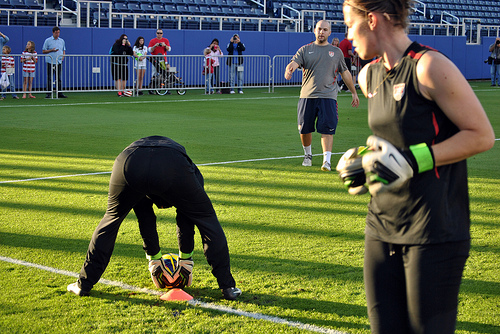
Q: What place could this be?
A: It is a field.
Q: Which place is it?
A: It is a field.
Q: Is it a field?
A: Yes, it is a field.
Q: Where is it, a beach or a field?
A: It is a field.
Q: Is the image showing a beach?
A: No, the picture is showing a field.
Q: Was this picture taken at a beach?
A: No, the picture was taken in a field.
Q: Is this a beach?
A: No, it is a field.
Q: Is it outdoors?
A: Yes, it is outdoors.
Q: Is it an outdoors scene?
A: Yes, it is outdoors.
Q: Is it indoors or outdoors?
A: It is outdoors.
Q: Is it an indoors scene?
A: No, it is outdoors.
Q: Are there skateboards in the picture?
A: No, there are no skateboards.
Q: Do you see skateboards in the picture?
A: No, there are no skateboards.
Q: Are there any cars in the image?
A: No, there are no cars.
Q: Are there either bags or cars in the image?
A: No, there are no cars or bags.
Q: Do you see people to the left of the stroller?
A: Yes, there is a person to the left of the stroller.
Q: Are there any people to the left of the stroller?
A: Yes, there is a person to the left of the stroller.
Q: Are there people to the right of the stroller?
A: No, the person is to the left of the stroller.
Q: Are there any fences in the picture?
A: Yes, there is a fence.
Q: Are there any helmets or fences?
A: Yes, there is a fence.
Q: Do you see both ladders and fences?
A: No, there is a fence but no ladders.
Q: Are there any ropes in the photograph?
A: No, there are no ropes.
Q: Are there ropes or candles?
A: No, there are no ropes or candles.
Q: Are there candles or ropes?
A: No, there are no ropes or candles.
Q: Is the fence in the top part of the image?
A: Yes, the fence is in the top of the image.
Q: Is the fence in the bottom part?
A: No, the fence is in the top of the image.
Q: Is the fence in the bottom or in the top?
A: The fence is in the top of the image.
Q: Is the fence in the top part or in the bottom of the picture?
A: The fence is in the top of the image.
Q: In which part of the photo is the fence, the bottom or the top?
A: The fence is in the top of the image.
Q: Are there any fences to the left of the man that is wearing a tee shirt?
A: Yes, there is a fence to the left of the man.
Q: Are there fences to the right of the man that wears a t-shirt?
A: No, the fence is to the left of the man.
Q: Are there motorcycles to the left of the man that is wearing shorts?
A: No, there is a fence to the left of the man.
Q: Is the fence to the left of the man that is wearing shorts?
A: Yes, the fence is to the left of the man.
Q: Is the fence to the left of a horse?
A: No, the fence is to the left of the man.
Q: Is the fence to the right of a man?
A: No, the fence is to the left of a man.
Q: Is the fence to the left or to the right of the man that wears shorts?
A: The fence is to the left of the man.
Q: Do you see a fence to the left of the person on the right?
A: Yes, there is a fence to the left of the person.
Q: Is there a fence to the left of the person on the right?
A: Yes, there is a fence to the left of the person.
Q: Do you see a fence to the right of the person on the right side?
A: No, the fence is to the left of the person.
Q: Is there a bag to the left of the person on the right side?
A: No, there is a fence to the left of the person.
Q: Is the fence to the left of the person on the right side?
A: Yes, the fence is to the left of the person.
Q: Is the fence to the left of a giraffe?
A: No, the fence is to the left of the person.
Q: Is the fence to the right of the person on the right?
A: No, the fence is to the left of the person.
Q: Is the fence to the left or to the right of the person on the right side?
A: The fence is to the left of the person.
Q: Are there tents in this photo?
A: No, there are no tents.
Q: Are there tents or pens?
A: No, there are no tents or pens.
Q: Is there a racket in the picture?
A: No, there are no rackets.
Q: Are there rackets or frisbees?
A: No, there are no rackets or frisbees.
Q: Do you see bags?
A: No, there are no bags.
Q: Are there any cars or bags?
A: No, there are no bags or cars.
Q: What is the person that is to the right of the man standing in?
A: The person is standing in the grass.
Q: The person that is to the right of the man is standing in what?
A: The person is standing in the grass.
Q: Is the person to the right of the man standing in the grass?
A: Yes, the person is standing in the grass.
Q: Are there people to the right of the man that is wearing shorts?
A: Yes, there is a person to the right of the man.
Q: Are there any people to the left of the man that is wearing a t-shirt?
A: No, the person is to the right of the man.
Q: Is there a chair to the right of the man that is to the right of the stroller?
A: No, there is a person to the right of the man.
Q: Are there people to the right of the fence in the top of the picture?
A: Yes, there is a person to the right of the fence.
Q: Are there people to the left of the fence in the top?
A: No, the person is to the right of the fence.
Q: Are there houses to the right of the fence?
A: No, there is a person to the right of the fence.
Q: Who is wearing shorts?
A: The man is wearing shorts.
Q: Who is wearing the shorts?
A: The man is wearing shorts.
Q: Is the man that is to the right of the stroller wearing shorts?
A: Yes, the man is wearing shorts.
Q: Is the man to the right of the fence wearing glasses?
A: No, the man is wearing shorts.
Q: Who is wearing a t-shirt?
A: The man is wearing a t-shirt.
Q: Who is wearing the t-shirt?
A: The man is wearing a t-shirt.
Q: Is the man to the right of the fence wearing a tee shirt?
A: Yes, the man is wearing a tee shirt.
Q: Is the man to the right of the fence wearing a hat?
A: No, the man is wearing a tee shirt.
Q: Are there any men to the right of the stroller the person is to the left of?
A: Yes, there is a man to the right of the stroller.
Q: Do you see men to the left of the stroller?
A: No, the man is to the right of the stroller.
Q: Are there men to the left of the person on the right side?
A: Yes, there is a man to the left of the person.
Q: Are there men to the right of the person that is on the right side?
A: No, the man is to the left of the person.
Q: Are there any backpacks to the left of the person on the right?
A: No, there is a man to the left of the person.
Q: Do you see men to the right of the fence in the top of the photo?
A: Yes, there is a man to the right of the fence.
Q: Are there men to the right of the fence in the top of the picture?
A: Yes, there is a man to the right of the fence.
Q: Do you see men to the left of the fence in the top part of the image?
A: No, the man is to the right of the fence.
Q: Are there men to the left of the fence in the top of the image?
A: No, the man is to the right of the fence.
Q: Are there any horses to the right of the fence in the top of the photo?
A: No, there is a man to the right of the fence.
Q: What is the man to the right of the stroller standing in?
A: The man is standing in the grass.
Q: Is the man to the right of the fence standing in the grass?
A: Yes, the man is standing in the grass.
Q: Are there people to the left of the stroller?
A: Yes, there is a person to the left of the stroller.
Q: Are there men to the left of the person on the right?
A: Yes, there is a man to the left of the person.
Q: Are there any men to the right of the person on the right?
A: No, the man is to the left of the person.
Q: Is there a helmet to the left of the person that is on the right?
A: No, there is a man to the left of the person.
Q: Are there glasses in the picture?
A: No, there are no glasses.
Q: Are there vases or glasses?
A: No, there are no glasses or vases.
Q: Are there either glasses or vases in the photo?
A: No, there are no glasses or vases.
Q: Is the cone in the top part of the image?
A: No, the cone is in the bottom of the image.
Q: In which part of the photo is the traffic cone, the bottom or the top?
A: The traffic cone is in the bottom of the image.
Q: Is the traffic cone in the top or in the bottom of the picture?
A: The traffic cone is in the bottom of the image.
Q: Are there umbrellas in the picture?
A: No, there are no umbrellas.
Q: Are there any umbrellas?
A: No, there are no umbrellas.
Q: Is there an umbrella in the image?
A: No, there are no umbrellas.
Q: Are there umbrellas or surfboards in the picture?
A: No, there are no umbrellas or surfboards.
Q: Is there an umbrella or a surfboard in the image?
A: No, there are no umbrellas or surfboards.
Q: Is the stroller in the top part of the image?
A: Yes, the stroller is in the top of the image.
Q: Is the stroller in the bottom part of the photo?
A: No, the stroller is in the top of the image.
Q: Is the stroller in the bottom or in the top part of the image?
A: The stroller is in the top of the image.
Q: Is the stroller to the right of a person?
A: Yes, the stroller is to the right of a person.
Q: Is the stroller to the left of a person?
A: No, the stroller is to the right of a person.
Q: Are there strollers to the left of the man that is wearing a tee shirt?
A: Yes, there is a stroller to the left of the man.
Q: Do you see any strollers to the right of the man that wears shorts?
A: No, the stroller is to the left of the man.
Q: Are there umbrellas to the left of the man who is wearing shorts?
A: No, there is a stroller to the left of the man.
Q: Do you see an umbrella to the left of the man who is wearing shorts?
A: No, there is a stroller to the left of the man.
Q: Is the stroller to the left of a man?
A: Yes, the stroller is to the left of a man.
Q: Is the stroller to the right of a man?
A: No, the stroller is to the left of a man.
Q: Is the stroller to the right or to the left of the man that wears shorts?
A: The stroller is to the left of the man.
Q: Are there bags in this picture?
A: No, there are no bags.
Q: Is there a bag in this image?
A: No, there are no bags.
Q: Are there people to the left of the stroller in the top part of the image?
A: Yes, there is a person to the left of the stroller.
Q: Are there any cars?
A: No, there are no cars.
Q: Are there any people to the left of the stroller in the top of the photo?
A: Yes, there is a person to the left of the stroller.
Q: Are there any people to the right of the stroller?
A: No, the person is to the left of the stroller.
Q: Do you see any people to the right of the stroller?
A: No, the person is to the left of the stroller.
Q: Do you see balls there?
A: Yes, there is a ball.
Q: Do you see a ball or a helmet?
A: Yes, there is a ball.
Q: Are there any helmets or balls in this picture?
A: Yes, there is a ball.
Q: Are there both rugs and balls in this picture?
A: No, there is a ball but no rugs.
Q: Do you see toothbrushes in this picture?
A: No, there are no toothbrushes.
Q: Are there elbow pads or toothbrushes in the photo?
A: No, there are no toothbrushes or elbow pads.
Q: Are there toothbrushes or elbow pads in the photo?
A: No, there are no toothbrushes or elbow pads.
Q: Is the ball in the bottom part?
A: Yes, the ball is in the bottom of the image.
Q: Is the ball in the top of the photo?
A: No, the ball is in the bottom of the image.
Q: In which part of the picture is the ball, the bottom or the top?
A: The ball is in the bottom of the image.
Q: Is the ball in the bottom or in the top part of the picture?
A: The ball is in the bottom of the image.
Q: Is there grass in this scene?
A: Yes, there is grass.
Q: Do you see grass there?
A: Yes, there is grass.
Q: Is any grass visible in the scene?
A: Yes, there is grass.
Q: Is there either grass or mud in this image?
A: Yes, there is grass.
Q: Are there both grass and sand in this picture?
A: No, there is grass but no sand.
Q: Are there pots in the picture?
A: No, there are no pots.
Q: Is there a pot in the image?
A: No, there are no pots.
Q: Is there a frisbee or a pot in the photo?
A: No, there are no pots or frisbees.